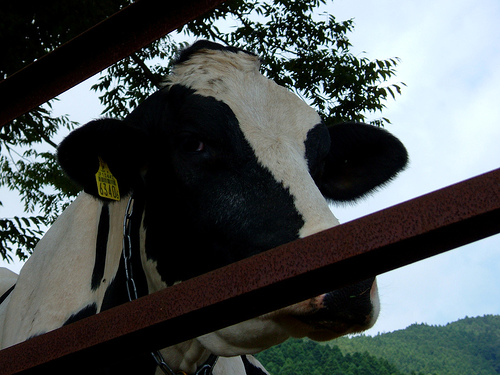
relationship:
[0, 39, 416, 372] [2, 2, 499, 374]
cow in fence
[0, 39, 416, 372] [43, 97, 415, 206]
cow has black ears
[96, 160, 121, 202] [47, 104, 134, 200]
tag in ear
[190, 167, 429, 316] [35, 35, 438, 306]
brown rail in front of cow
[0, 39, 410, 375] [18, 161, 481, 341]
cow behind fence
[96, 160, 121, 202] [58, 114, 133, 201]
tag in ear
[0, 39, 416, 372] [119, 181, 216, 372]
cow has chain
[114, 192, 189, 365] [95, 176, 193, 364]
chain on neck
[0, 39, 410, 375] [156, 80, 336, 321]
cow has head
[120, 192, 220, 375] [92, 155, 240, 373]
chain on neck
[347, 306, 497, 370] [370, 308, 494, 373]
tree on mountain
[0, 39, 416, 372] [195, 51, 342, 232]
cow has stripe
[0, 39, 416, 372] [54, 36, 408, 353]
cow has head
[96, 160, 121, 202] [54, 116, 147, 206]
tag in black ears